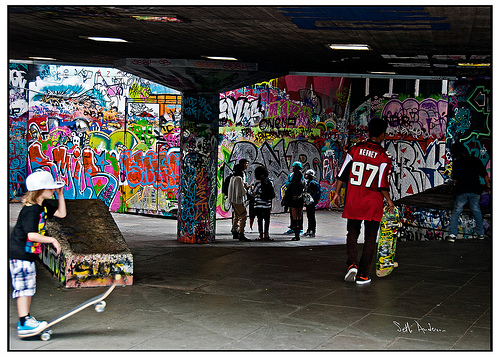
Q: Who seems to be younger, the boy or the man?
A: The boy is younger than the man.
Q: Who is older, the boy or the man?
A: The man is older than the boy.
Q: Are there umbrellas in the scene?
A: No, there are no umbrellas.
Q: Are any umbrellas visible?
A: No, there are no umbrellas.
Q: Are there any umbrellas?
A: No, there are no umbrellas.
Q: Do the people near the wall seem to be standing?
A: Yes, the people are standing.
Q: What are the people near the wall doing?
A: The people are standing.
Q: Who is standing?
A: The people are standing.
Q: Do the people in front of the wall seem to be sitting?
A: No, the people are standing.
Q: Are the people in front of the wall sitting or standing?
A: The people are standing.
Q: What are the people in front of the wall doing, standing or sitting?
A: The people are standing.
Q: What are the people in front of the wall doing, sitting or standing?
A: The people are standing.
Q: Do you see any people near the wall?
A: Yes, there are people near the wall.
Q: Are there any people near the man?
A: Yes, there are people near the man.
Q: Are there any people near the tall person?
A: Yes, there are people near the man.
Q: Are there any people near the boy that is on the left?
A: Yes, there are people near the boy.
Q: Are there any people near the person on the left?
A: Yes, there are people near the boy.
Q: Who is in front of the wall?
A: The people are in front of the wall.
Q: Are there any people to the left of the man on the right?
A: Yes, there are people to the left of the man.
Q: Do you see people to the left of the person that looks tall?
A: Yes, there are people to the left of the man.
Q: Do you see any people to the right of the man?
A: No, the people are to the left of the man.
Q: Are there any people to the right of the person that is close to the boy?
A: No, the people are to the left of the man.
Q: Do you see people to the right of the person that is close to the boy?
A: No, the people are to the left of the man.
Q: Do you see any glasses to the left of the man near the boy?
A: No, there are people to the left of the man.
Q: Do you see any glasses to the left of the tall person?
A: No, there are people to the left of the man.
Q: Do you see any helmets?
A: No, there are no helmets.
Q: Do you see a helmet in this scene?
A: No, there are no helmets.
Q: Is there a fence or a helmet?
A: No, there are no helmets or fences.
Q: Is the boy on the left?
A: Yes, the boy is on the left of the image.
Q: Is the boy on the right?
A: No, the boy is on the left of the image.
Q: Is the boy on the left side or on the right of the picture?
A: The boy is on the left of the image.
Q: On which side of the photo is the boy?
A: The boy is on the left of the image.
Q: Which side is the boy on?
A: The boy is on the left of the image.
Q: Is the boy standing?
A: Yes, the boy is standing.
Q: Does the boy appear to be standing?
A: Yes, the boy is standing.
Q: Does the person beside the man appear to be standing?
A: Yes, the boy is standing.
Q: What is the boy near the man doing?
A: The boy is standing.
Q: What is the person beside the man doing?
A: The boy is standing.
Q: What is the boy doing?
A: The boy is standing.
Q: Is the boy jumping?
A: No, the boy is standing.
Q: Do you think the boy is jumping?
A: No, the boy is standing.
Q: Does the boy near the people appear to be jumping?
A: No, the boy is standing.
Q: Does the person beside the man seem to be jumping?
A: No, the boy is standing.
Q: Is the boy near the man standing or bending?
A: The boy is standing.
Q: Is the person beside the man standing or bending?
A: The boy is standing.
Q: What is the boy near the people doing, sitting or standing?
A: The boy is standing.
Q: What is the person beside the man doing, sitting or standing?
A: The boy is standing.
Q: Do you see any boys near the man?
A: Yes, there is a boy near the man.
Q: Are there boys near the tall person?
A: Yes, there is a boy near the man.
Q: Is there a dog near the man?
A: No, there is a boy near the man.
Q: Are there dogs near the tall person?
A: No, there is a boy near the man.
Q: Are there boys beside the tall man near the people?
A: Yes, there is a boy beside the man.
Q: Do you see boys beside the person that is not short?
A: Yes, there is a boy beside the man.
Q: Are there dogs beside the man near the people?
A: No, there is a boy beside the man.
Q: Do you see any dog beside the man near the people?
A: No, there is a boy beside the man.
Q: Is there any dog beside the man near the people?
A: No, there is a boy beside the man.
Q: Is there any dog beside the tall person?
A: No, there is a boy beside the man.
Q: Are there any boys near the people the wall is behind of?
A: Yes, there is a boy near the people.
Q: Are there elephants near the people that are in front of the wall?
A: No, there is a boy near the people.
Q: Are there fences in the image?
A: No, there are no fences.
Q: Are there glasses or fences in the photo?
A: No, there are no fences or glasses.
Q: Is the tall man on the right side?
A: Yes, the man is on the right of the image.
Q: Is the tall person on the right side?
A: Yes, the man is on the right of the image.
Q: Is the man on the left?
A: No, the man is on the right of the image.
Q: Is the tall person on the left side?
A: No, the man is on the right of the image.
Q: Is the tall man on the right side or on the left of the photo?
A: The man is on the right of the image.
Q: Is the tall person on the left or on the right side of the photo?
A: The man is on the right of the image.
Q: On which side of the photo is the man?
A: The man is on the right of the image.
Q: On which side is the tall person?
A: The man is on the right of the image.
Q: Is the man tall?
A: Yes, the man is tall.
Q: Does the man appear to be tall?
A: Yes, the man is tall.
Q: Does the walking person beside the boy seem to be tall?
A: Yes, the man is tall.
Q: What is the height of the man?
A: The man is tall.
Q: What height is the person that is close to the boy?
A: The man is tall.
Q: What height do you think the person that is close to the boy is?
A: The man is tall.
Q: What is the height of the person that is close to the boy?
A: The man is tall.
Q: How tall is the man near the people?
A: The man is tall.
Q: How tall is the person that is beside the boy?
A: The man is tall.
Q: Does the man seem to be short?
A: No, the man is tall.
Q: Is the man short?
A: No, the man is tall.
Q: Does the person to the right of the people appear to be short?
A: No, the man is tall.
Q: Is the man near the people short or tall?
A: The man is tall.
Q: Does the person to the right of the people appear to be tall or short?
A: The man is tall.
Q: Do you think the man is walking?
A: Yes, the man is walking.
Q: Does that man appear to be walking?
A: Yes, the man is walking.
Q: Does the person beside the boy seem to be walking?
A: Yes, the man is walking.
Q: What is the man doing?
A: The man is walking.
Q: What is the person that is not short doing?
A: The man is walking.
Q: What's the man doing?
A: The man is walking.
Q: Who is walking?
A: The man is walking.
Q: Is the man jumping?
A: No, the man is walking.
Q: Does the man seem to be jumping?
A: No, the man is walking.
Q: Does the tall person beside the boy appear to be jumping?
A: No, the man is walking.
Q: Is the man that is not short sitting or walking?
A: The man is walking.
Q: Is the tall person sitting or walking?
A: The man is walking.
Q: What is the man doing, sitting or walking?
A: The man is walking.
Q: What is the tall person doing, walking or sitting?
A: The man is walking.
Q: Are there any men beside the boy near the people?
A: Yes, there is a man beside the boy.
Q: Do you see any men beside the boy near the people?
A: Yes, there is a man beside the boy.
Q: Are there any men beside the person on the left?
A: Yes, there is a man beside the boy.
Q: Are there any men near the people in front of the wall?
A: Yes, there is a man near the people.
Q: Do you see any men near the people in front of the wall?
A: Yes, there is a man near the people.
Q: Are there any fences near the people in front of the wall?
A: No, there is a man near the people.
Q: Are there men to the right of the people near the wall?
A: Yes, there is a man to the right of the people.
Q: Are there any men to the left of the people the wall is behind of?
A: No, the man is to the right of the people.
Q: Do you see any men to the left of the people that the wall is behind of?
A: No, the man is to the right of the people.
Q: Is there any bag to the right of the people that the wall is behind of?
A: No, there is a man to the right of the people.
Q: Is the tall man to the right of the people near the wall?
A: Yes, the man is to the right of the people.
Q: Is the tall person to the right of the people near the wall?
A: Yes, the man is to the right of the people.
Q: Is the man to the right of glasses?
A: No, the man is to the right of the people.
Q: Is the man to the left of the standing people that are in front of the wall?
A: No, the man is to the right of the people.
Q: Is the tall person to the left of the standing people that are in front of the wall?
A: No, the man is to the right of the people.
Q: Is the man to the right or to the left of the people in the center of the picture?
A: The man is to the right of the people.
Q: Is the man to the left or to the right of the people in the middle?
A: The man is to the right of the people.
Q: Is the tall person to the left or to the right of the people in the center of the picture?
A: The man is to the right of the people.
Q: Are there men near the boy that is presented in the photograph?
A: Yes, there is a man near the boy.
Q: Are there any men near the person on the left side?
A: Yes, there is a man near the boy.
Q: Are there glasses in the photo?
A: No, there are no glasses.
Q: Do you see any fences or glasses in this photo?
A: No, there are no glasses or fences.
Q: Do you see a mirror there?
A: No, there are no mirrors.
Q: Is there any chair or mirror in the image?
A: No, there are no mirrors or chairs.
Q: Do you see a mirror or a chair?
A: No, there are no mirrors or chairs.